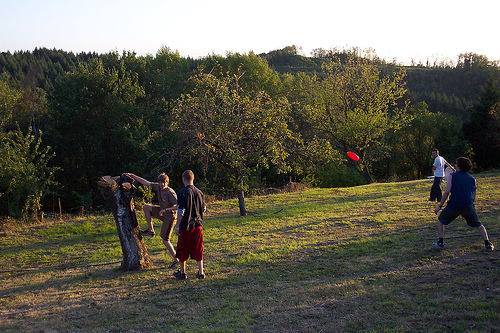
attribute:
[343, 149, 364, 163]
frisbee — red, flying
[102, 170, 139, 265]
tree stump — old, treestump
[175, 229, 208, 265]
shorts — red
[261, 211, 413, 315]
grass — dry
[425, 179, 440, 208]
pants — long, black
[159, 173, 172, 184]
hair — red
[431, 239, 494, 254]
sneaker feet — white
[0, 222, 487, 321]
field — grassy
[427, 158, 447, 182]
shirt — white, blue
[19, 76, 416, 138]
trees — green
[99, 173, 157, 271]
treebark — brown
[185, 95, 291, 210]
tree — green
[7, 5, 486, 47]
sky — blue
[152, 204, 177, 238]
shorts — tan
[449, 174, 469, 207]
top — blue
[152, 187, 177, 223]
shirt — brown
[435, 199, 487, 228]
shorts — black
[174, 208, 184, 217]
undershirt — white